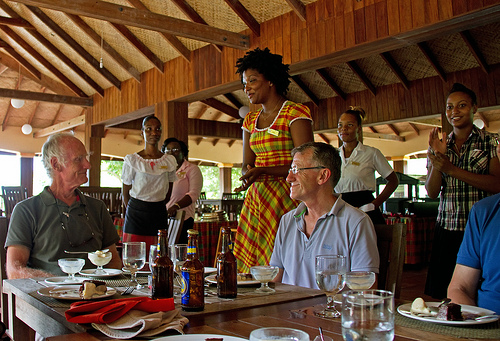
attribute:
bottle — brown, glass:
[183, 228, 205, 309]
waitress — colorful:
[232, 47, 316, 277]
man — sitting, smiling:
[270, 142, 377, 291]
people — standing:
[123, 115, 204, 245]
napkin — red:
[66, 296, 175, 323]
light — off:
[23, 124, 33, 134]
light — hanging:
[99, 62, 104, 69]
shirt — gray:
[4, 185, 121, 272]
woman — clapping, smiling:
[425, 82, 499, 301]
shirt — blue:
[456, 192, 499, 314]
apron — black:
[340, 190, 388, 223]